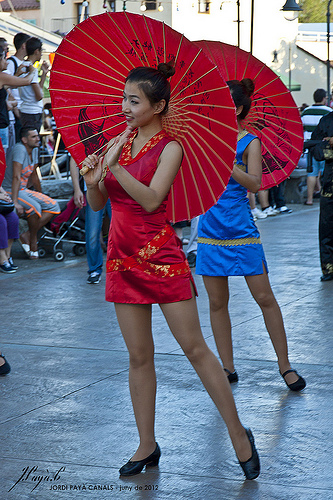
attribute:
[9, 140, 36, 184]
shirt — grey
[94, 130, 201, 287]
dress — red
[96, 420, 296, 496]
shoes — black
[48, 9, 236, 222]
umbrella — red, large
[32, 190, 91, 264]
carriage — red, silver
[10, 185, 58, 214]
shorts — orange, grey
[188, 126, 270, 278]
dress — blue